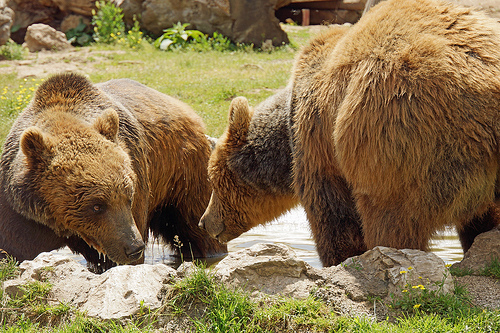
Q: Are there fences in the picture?
A: No, there are no fences.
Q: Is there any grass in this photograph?
A: Yes, there is grass.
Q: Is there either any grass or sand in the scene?
A: Yes, there is grass.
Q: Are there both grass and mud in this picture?
A: No, there is grass but no mud.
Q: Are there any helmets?
A: No, there are no helmets.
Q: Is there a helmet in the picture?
A: No, there are no helmets.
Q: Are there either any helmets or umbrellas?
A: No, there are no helmets or umbrellas.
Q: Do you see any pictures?
A: No, there are no pictures.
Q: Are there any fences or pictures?
A: No, there are no pictures or fences.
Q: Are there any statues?
A: No, there are no statues.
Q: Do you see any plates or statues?
A: No, there are no statues or plates.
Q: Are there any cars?
A: No, there are no cars.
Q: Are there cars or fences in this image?
A: No, there are no cars or fences.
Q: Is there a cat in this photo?
A: No, there are no cats.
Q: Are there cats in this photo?
A: No, there are no cats.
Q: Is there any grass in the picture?
A: Yes, there is grass.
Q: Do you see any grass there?
A: Yes, there is grass.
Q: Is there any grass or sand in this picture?
A: Yes, there is grass.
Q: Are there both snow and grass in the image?
A: No, there is grass but no snow.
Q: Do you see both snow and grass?
A: No, there is grass but no snow.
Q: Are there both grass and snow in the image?
A: No, there is grass but no snow.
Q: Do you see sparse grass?
A: Yes, there is sparse grass.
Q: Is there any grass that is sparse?
A: Yes, there is grass that is sparse.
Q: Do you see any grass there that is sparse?
A: Yes, there is grass that is sparse.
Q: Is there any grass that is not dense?
A: Yes, there is sparse grass.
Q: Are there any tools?
A: No, there are no tools.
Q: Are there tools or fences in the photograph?
A: No, there are no tools or fences.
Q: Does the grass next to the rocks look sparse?
A: Yes, the grass is sparse.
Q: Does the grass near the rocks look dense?
A: No, the grass is sparse.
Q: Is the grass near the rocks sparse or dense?
A: The grass is sparse.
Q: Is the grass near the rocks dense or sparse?
A: The grass is sparse.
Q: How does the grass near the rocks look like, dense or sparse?
A: The grass is sparse.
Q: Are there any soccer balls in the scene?
A: No, there are no soccer balls.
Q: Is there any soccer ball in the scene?
A: No, there are no soccer balls.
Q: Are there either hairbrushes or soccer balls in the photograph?
A: No, there are no soccer balls or hairbrushes.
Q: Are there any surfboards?
A: No, there are no surfboards.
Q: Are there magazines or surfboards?
A: No, there are no surfboards or magazines.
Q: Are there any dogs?
A: No, there are no dogs.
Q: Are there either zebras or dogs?
A: No, there are no dogs or zebras.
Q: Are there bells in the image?
A: No, there are no bells.